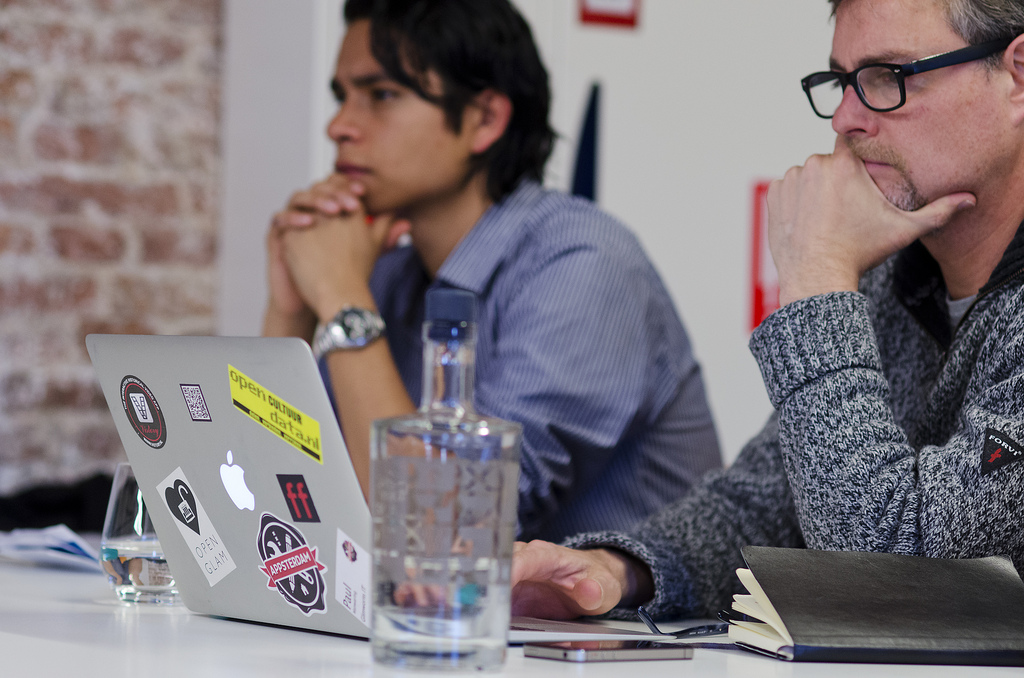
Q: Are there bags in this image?
A: No, there are no bags.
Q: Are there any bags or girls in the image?
A: No, there are no bags or girls.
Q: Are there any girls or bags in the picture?
A: No, there are no bags or girls.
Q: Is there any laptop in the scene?
A: Yes, there is a laptop.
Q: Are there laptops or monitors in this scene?
A: Yes, there is a laptop.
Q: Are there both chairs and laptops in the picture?
A: No, there is a laptop but no chairs.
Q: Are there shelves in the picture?
A: No, there are no shelves.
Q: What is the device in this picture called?
A: The device is a laptop.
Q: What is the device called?
A: The device is a laptop.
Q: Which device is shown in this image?
A: The device is a laptop.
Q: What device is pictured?
A: The device is a laptop.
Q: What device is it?
A: The device is a laptop.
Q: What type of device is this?
A: This is a laptop.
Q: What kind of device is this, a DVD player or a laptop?
A: This is a laptop.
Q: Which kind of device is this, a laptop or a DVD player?
A: This is a laptop.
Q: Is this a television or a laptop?
A: This is a laptop.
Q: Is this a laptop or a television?
A: This is a laptop.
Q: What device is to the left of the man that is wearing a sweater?
A: The device is a laptop.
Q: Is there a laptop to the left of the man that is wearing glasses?
A: Yes, there is a laptop to the left of the man.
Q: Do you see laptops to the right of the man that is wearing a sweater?
A: No, the laptop is to the left of the man.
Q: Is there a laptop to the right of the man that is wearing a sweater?
A: No, the laptop is to the left of the man.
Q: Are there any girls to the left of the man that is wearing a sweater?
A: No, there is a laptop to the left of the man.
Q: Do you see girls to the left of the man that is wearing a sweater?
A: No, there is a laptop to the left of the man.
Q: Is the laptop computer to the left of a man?
A: Yes, the laptop computer is to the left of a man.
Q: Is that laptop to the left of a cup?
A: No, the laptop is to the left of a man.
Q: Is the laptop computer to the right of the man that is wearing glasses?
A: No, the laptop computer is to the left of the man.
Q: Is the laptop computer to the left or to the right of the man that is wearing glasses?
A: The laptop computer is to the left of the man.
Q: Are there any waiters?
A: No, there are no waiters.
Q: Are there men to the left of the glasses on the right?
A: Yes, there is a man to the left of the glasses.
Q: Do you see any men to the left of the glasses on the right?
A: Yes, there is a man to the left of the glasses.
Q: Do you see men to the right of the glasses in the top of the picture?
A: No, the man is to the left of the glasses.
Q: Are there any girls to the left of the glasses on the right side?
A: No, there is a man to the left of the glasses.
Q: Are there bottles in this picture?
A: Yes, there is a bottle.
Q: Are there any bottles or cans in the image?
A: Yes, there is a bottle.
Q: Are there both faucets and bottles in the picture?
A: No, there is a bottle but no faucets.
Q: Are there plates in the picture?
A: No, there are no plates.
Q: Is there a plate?
A: No, there are no plates.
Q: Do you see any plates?
A: No, there are no plates.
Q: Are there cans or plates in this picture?
A: No, there are no plates or cans.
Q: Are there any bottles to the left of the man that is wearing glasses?
A: Yes, there is a bottle to the left of the man.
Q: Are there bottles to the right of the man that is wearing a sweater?
A: No, the bottle is to the left of the man.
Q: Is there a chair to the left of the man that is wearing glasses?
A: No, there is a bottle to the left of the man.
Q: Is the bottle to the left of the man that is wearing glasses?
A: Yes, the bottle is to the left of the man.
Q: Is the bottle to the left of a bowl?
A: No, the bottle is to the left of the man.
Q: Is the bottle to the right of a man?
A: No, the bottle is to the left of a man.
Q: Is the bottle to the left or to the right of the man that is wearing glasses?
A: The bottle is to the left of the man.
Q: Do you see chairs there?
A: No, there are no chairs.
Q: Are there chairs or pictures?
A: No, there are no chairs or pictures.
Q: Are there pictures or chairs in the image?
A: No, there are no chairs or pictures.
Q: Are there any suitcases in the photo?
A: No, there are no suitcases.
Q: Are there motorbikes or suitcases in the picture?
A: No, there are no suitcases or motorbikes.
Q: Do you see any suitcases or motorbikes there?
A: No, there are no suitcases or motorbikes.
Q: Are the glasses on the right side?
A: Yes, the glasses are on the right of the image.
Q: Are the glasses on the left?
A: No, the glasses are on the right of the image.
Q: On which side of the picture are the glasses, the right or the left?
A: The glasses are on the right of the image.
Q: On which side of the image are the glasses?
A: The glasses are on the right of the image.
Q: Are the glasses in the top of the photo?
A: Yes, the glasses are in the top of the image.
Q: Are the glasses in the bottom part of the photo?
A: No, the glasses are in the top of the image.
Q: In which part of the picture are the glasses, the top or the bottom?
A: The glasses are in the top of the image.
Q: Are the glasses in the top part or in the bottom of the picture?
A: The glasses are in the top of the image.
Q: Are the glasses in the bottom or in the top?
A: The glasses are in the top of the image.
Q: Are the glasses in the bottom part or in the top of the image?
A: The glasses are in the top of the image.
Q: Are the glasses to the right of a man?
A: Yes, the glasses are to the right of a man.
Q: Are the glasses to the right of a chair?
A: No, the glasses are to the right of a man.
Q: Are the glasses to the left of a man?
A: No, the glasses are to the right of a man.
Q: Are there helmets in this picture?
A: No, there are no helmets.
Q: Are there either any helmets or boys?
A: No, there are no helmets or boys.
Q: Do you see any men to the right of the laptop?
A: Yes, there is a man to the right of the laptop.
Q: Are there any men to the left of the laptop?
A: No, the man is to the right of the laptop.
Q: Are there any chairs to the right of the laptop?
A: No, there is a man to the right of the laptop.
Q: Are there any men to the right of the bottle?
A: Yes, there is a man to the right of the bottle.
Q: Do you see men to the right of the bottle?
A: Yes, there is a man to the right of the bottle.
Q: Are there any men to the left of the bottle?
A: No, the man is to the right of the bottle.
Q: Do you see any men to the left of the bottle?
A: No, the man is to the right of the bottle.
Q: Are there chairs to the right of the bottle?
A: No, there is a man to the right of the bottle.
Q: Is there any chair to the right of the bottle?
A: No, there is a man to the right of the bottle.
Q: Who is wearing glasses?
A: The man is wearing glasses.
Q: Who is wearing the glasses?
A: The man is wearing glasses.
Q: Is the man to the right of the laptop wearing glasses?
A: Yes, the man is wearing glasses.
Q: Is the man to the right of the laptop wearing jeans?
A: No, the man is wearing glasses.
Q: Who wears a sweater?
A: The man wears a sweater.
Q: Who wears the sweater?
A: The man wears a sweater.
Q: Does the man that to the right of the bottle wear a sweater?
A: Yes, the man wears a sweater.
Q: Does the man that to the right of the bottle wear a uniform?
A: No, the man wears a sweater.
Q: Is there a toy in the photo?
A: No, there are no toys.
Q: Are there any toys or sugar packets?
A: No, there are no toys or sugar packets.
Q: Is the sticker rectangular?
A: Yes, the sticker is rectangular.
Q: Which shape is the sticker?
A: The sticker is rectangular.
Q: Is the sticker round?
A: No, the sticker is rectangular.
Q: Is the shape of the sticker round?
A: No, the sticker is rectangular.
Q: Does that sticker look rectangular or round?
A: The sticker is rectangular.